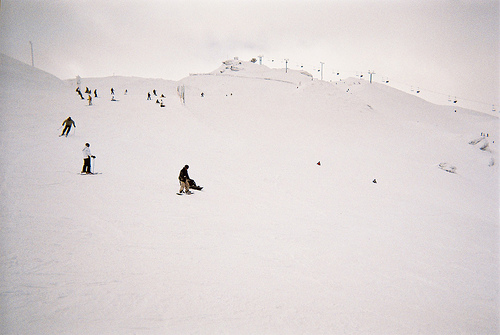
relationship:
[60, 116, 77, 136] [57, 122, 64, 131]
person with pole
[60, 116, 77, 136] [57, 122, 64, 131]
person has a pole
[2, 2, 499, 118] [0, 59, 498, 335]
sky above slope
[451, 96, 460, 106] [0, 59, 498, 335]
chair on slope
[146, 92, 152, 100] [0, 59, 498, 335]
skier on slope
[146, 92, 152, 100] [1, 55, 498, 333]
skier on mountain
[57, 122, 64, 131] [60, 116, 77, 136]
pole with person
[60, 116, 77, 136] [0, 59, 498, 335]
person coming down slope